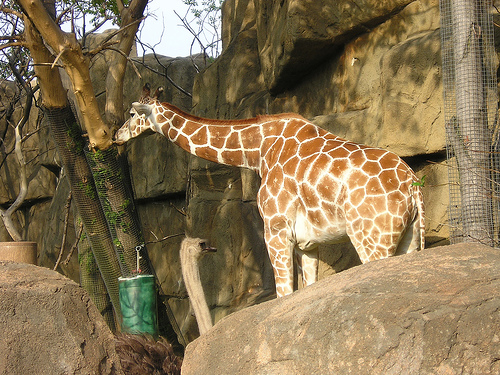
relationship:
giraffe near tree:
[108, 86, 432, 267] [13, 0, 204, 325]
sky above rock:
[3, 1, 227, 72] [4, 261, 107, 374]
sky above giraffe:
[3, 1, 227, 72] [108, 86, 432, 267]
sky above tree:
[3, 1, 227, 72] [13, 0, 204, 325]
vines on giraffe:
[75, 142, 134, 261] [108, 86, 432, 267]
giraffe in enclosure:
[108, 86, 432, 267] [3, 28, 475, 372]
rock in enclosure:
[179, 229, 477, 373] [3, 28, 475, 372]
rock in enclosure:
[2, 256, 118, 373] [3, 28, 475, 372]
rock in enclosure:
[4, 261, 107, 374] [3, 28, 475, 372]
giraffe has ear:
[111, 81, 432, 301] [129, 98, 156, 119]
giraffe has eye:
[111, 81, 432, 301] [126, 111, 136, 121]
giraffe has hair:
[111, 81, 432, 301] [152, 97, 299, 127]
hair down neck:
[152, 97, 299, 127] [154, 106, 297, 176]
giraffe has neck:
[111, 81, 432, 301] [154, 106, 297, 176]